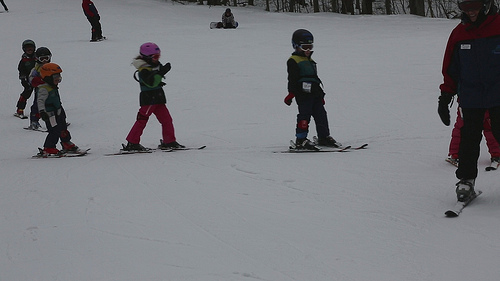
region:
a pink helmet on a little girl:
[135, 38, 162, 63]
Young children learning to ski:
[18, 28, 368, 160]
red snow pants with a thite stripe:
[128, 104, 175, 151]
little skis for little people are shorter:
[23, 139, 94, 161]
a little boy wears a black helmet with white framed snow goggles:
[290, 25, 316, 57]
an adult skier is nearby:
[440, 6, 497, 216]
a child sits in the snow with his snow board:
[208, 5, 240, 32]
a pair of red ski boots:
[40, 135, 81, 156]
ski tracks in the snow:
[0, 0, 498, 280]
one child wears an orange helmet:
[39, 59, 62, 80]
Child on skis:
[95, 138, 210, 162]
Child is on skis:
[98, 138, 208, 158]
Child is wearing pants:
[123, 98, 180, 147]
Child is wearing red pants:
[125, 95, 179, 146]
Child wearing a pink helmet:
[135, 39, 165, 66]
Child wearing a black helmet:
[288, 23, 313, 50]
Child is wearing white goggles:
[289, 38, 319, 50]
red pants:
[154, 111, 173, 143]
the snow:
[193, 229, 278, 280]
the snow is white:
[208, 215, 293, 265]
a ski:
[441, 202, 458, 220]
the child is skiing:
[283, 27, 366, 164]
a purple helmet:
[138, 42, 156, 57]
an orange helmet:
[41, 63, 58, 73]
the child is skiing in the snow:
[118, 44, 200, 156]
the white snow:
[192, 40, 260, 93]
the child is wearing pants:
[313, 104, 330, 141]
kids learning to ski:
[8, 30, 465, 187]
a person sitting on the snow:
[211, 5, 253, 42]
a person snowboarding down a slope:
[61, 2, 133, 42]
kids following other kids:
[13, 31, 203, 177]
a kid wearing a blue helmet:
[259, 26, 343, 62]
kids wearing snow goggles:
[18, 41, 380, 78]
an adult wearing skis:
[431, 144, 497, 226]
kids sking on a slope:
[14, 39, 396, 198]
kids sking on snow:
[21, 36, 453, 230]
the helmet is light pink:
[143, 44, 155, 54]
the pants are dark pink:
[161, 112, 174, 134]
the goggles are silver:
[299, 41, 316, 54]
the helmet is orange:
[45, 66, 55, 73]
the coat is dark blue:
[464, 53, 486, 77]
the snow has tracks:
[232, 160, 274, 187]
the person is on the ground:
[211, 7, 246, 32]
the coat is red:
[458, 27, 475, 39]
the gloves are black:
[433, 87, 453, 122]